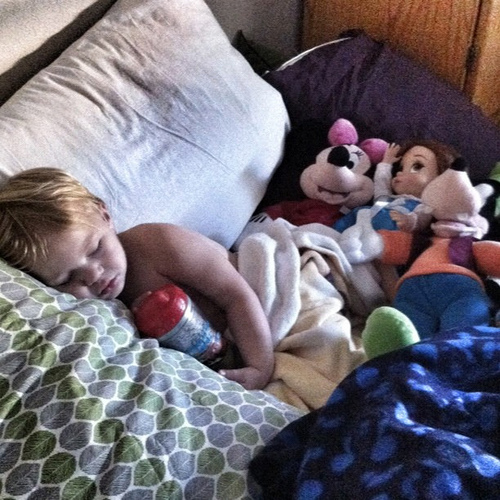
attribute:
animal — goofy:
[363, 158, 499, 372]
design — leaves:
[2, 258, 312, 498]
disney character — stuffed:
[252, 117, 394, 231]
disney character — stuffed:
[334, 135, 461, 257]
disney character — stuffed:
[361, 154, 499, 357]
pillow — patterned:
[0, 262, 307, 498]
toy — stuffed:
[252, 116, 388, 248]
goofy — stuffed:
[359, 151, 499, 364]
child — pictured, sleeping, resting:
[0, 166, 275, 392]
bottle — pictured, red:
[138, 284, 215, 358]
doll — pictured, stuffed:
[387, 130, 444, 227]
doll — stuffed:
[387, 156, 499, 339]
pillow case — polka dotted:
[1, 302, 294, 498]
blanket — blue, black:
[248, 317, 498, 496]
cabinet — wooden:
[310, 1, 499, 82]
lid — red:
[140, 285, 187, 331]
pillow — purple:
[282, 23, 478, 134]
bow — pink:
[333, 116, 386, 157]